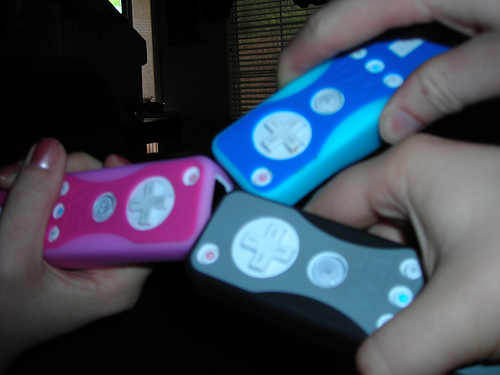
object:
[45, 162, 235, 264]
controller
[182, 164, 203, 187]
button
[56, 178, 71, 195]
button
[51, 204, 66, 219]
button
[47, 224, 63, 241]
button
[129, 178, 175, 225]
button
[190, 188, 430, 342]
controller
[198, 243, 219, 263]
button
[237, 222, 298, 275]
button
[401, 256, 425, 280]
button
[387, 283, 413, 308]
button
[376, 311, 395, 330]
button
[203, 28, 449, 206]
controller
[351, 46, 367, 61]
button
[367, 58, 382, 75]
button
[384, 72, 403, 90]
button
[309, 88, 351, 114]
button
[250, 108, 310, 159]
button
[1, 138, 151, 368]
hand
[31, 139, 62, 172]
pink nail polish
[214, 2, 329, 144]
window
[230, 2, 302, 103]
blinds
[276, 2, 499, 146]
hand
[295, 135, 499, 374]
hand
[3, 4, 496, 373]
room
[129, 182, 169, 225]
cross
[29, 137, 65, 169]
finger nail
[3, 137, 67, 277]
thumb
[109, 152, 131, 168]
finger nail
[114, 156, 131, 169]
nail polish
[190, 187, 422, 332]
surface